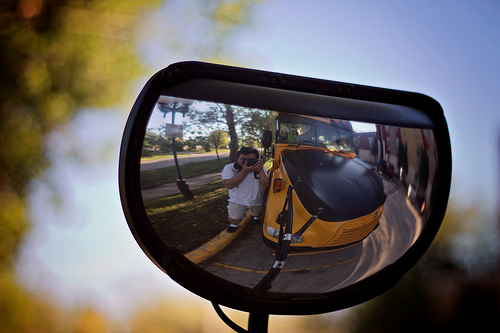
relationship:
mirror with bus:
[116, 59, 462, 305] [261, 111, 388, 253]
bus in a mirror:
[261, 115, 374, 244] [116, 59, 462, 305]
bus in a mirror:
[261, 111, 388, 253] [116, 59, 462, 305]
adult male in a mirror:
[221, 147, 274, 234] [103, 47, 470, 324]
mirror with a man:
[116, 59, 462, 305] [213, 132, 276, 239]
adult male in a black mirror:
[221, 147, 274, 234] [261, 130, 274, 150]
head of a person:
[230, 140, 271, 180] [220, 133, 270, 239]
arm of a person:
[214, 149, 244, 185] [221, 147, 265, 237]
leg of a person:
[225, 199, 240, 230] [214, 135, 274, 250]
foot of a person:
[228, 220, 242, 236] [218, 140, 281, 246]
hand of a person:
[243, 164, 258, 180] [214, 132, 271, 220]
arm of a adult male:
[221, 164, 244, 189] [221, 147, 274, 234]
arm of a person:
[221, 164, 244, 189] [219, 127, 266, 229]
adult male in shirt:
[217, 140, 275, 244] [227, 160, 270, 204]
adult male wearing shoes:
[221, 147, 274, 234] [218, 217, 269, 234]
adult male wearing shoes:
[221, 147, 274, 234] [224, 207, 285, 227]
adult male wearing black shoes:
[221, 147, 274, 234] [217, 207, 271, 247]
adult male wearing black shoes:
[221, 147, 274, 234] [226, 224, 240, 233]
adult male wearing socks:
[221, 147, 274, 234] [228, 225, 268, 233]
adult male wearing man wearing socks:
[221, 147, 274, 234] [229, 223, 238, 228]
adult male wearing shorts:
[221, 147, 274, 234] [224, 189, 276, 225]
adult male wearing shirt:
[221, 147, 274, 234] [224, 171, 277, 207]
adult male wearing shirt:
[221, 147, 274, 234] [220, 160, 269, 207]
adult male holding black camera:
[221, 147, 274, 234] [240, 156, 266, 174]